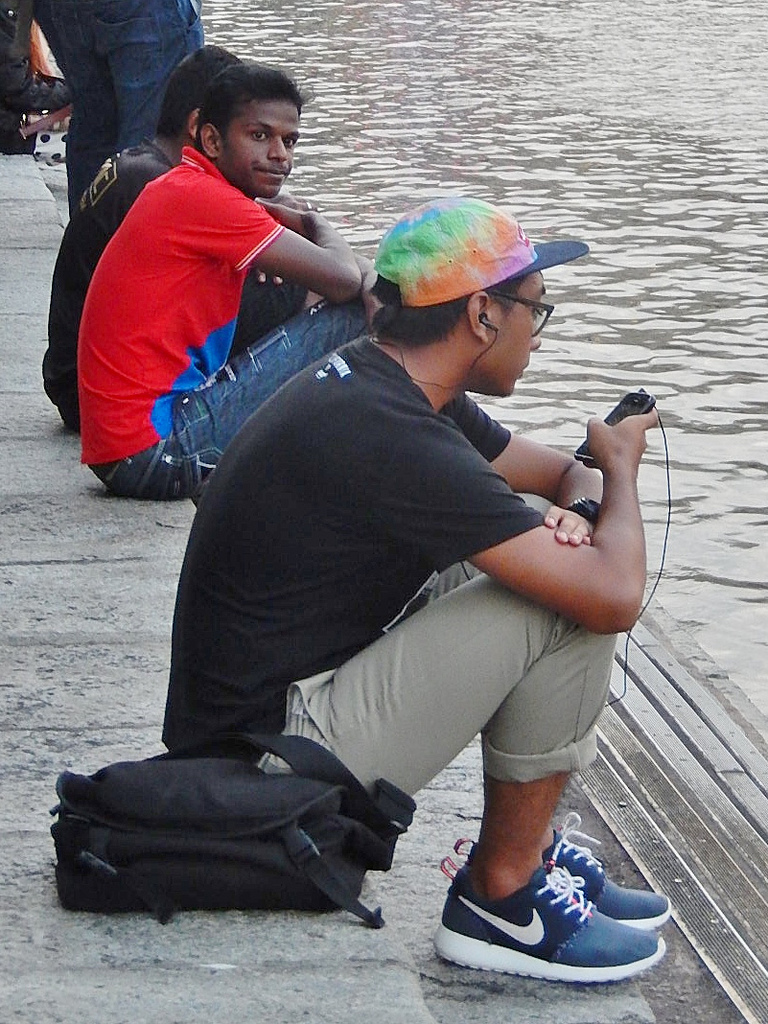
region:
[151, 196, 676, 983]
A young man lookin at a phone.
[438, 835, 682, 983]
Blue and white tennis shoes.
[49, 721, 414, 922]
A black canvas tote on the ground.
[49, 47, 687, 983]
A group of young men sitting by the water.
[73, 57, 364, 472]
A boy with a red shirt.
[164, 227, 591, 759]
A boy in a black shirt.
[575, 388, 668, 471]
A black ceil phone.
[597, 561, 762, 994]
Steps to the waters edge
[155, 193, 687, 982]
A boy wearing a ball cap.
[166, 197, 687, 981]
A boy with earplugs in his ears.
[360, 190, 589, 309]
colorful hat on mans head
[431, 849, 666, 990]
mans left blue and white nike tennis shoe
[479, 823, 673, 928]
mans right blue and white nike tennis shoe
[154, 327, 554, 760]
t shirt on man wearing colorful hat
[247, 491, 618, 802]
rolled up khaki pants on man with colorful hat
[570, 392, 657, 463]
device in mans hand with colorful cap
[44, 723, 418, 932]
backpack sitting next to man with colorful hat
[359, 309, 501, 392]
earbud in the man with the colorful hat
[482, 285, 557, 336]
glasses of the man with the colorful hat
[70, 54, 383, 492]
man dressed in red shirt and blue jeans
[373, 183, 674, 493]
a man is looking at his mobile phone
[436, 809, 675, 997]
a pair of blue Nike sneakers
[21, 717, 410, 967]
a black bag on the floor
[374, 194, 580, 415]
a man wearing a colorful cap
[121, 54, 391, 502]
a man wearing a red shirt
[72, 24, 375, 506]
a man wearing blue denim jeans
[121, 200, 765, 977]
a man sitting next to a river bank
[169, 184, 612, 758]
a man wearing a black shirt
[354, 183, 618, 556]
a man wearing a black watch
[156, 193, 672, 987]
young boy wearing a cap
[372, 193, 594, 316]
the cap is multi-colored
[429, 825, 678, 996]
sneakers are blue and white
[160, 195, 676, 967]
young boy wearing ear buds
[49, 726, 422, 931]
black bag next to boy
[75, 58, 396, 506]
young man wearing red shirt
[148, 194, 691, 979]
young man sitting by the water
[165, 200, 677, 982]
boy wearing black shirt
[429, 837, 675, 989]
sneakers have nike logo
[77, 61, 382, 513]
young man with black hair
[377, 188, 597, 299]
a colorful pastel hat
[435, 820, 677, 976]
blue and white nike shoes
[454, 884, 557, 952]
a nike swoosh symbol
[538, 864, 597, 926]
a white shoelace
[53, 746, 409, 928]
a black book bag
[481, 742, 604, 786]
a rolled pant cuff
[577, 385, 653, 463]
a black cell phone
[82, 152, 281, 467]
a red short sleeved shirt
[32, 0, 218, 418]
a pair of denim jeans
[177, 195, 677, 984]
a young man sits by the water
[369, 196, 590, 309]
the young man wears a rainbow colored cap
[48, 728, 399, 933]
a black backpack is on the ground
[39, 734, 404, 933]
the backpack is next to the young man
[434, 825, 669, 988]
the young man wears sneakers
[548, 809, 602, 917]
the sneakers have white shoelaces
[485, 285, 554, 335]
the young man wears glasses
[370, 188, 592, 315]
tie dye hat on a man's head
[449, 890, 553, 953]
nike swoosh on a blue shoe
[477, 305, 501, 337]
ear bud in a man's right ear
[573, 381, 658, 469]
i phone in a man's hand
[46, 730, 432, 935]
black backpack on the concrete